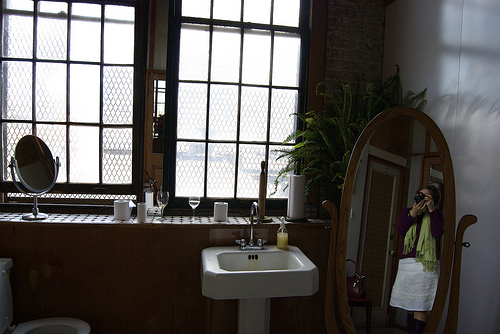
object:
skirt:
[387, 257, 440, 312]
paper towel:
[286, 174, 307, 219]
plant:
[269, 64, 428, 219]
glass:
[189, 192, 201, 220]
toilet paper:
[213, 201, 228, 222]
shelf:
[0, 210, 319, 235]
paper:
[114, 199, 130, 221]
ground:
[322, 127, 344, 165]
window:
[0, 0, 137, 184]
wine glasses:
[189, 192, 201, 221]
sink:
[192, 238, 330, 298]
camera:
[413, 191, 425, 204]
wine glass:
[156, 188, 170, 221]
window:
[174, 0, 299, 199]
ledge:
[0, 209, 326, 226]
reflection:
[347, 115, 444, 333]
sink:
[215, 250, 305, 271]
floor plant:
[426, 94, 496, 222]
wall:
[415, 0, 500, 83]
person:
[386, 184, 441, 333]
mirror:
[345, 121, 443, 334]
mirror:
[11, 134, 59, 192]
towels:
[287, 175, 305, 219]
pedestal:
[236, 297, 271, 333]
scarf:
[402, 215, 438, 272]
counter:
[0, 211, 196, 323]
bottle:
[276, 223, 288, 248]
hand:
[412, 199, 427, 211]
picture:
[0, 27, 500, 334]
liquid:
[189, 200, 200, 208]